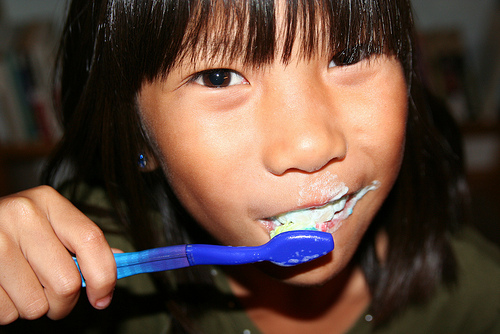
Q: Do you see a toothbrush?
A: Yes, there is a toothbrush.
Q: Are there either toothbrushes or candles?
A: Yes, there is a toothbrush.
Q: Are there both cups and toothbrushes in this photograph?
A: No, there is a toothbrush but no cups.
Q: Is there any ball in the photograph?
A: No, there are no balls.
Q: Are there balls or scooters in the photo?
A: No, there are no balls or scooters.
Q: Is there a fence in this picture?
A: No, there are no fences.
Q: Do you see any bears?
A: No, there are no bears.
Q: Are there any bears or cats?
A: No, there are no bears or cats.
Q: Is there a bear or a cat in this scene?
A: No, there are no bears or cats.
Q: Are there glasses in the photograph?
A: No, there are no glasses.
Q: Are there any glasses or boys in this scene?
A: No, there are no glasses or boys.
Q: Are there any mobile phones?
A: No, there are no mobile phones.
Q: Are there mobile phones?
A: No, there are no mobile phones.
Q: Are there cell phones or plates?
A: No, there are no cell phones or plates.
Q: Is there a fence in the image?
A: No, there are no fences.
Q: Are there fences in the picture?
A: No, there are no fences.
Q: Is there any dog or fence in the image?
A: No, there are no fences or dogs.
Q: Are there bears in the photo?
A: No, there are no bears.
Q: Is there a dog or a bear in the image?
A: No, there are no bears or dogs.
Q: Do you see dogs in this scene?
A: No, there are no dogs.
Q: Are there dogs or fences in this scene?
A: No, there are no dogs or fences.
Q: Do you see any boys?
A: No, there are no boys.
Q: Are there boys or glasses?
A: No, there are no boys or glasses.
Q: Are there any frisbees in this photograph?
A: No, there are no frisbees.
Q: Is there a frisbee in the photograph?
A: No, there are no frisbees.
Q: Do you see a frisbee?
A: No, there are no frisbees.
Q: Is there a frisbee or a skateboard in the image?
A: No, there are no frisbees or skateboards.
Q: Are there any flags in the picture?
A: No, there are no flags.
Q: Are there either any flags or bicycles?
A: No, there are no flags or bicycles.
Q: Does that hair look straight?
A: Yes, the hair is straight.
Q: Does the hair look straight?
A: Yes, the hair is straight.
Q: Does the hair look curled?
A: No, the hair is straight.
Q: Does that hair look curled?
A: No, the hair is straight.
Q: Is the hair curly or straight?
A: The hair is straight.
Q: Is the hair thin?
A: Yes, the hair is thin.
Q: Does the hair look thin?
A: Yes, the hair is thin.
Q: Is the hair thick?
A: No, the hair is thin.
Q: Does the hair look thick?
A: No, the hair is thin.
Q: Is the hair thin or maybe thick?
A: The hair is thin.